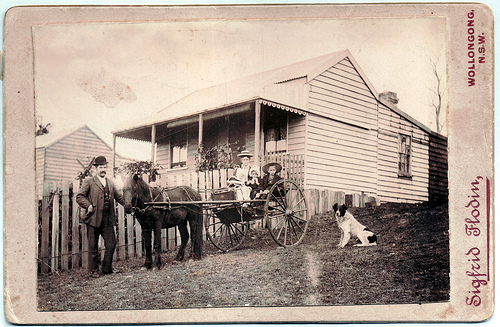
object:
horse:
[112, 167, 205, 270]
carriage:
[143, 178, 309, 248]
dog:
[331, 201, 379, 247]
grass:
[37, 200, 451, 308]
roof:
[114, 47, 380, 135]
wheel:
[264, 178, 311, 247]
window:
[265, 112, 287, 154]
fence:
[39, 153, 304, 276]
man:
[76, 155, 134, 278]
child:
[247, 162, 286, 208]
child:
[246, 165, 261, 198]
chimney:
[379, 90, 397, 105]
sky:
[36, 22, 456, 163]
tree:
[428, 56, 442, 132]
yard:
[37, 181, 446, 304]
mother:
[228, 150, 258, 206]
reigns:
[120, 190, 141, 213]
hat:
[262, 158, 282, 173]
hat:
[94, 154, 110, 167]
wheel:
[204, 187, 250, 250]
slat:
[289, 55, 427, 203]